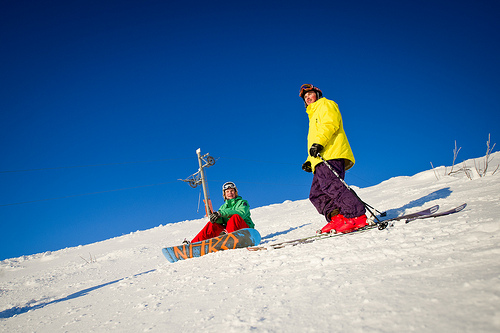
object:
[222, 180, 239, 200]
helmet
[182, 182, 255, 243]
boy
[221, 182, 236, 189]
googles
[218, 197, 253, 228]
jacket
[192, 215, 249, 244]
pants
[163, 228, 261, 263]
snowboard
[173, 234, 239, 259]
letters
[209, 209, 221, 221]
gloves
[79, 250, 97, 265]
weeds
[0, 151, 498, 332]
snow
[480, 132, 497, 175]
branches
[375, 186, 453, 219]
shadow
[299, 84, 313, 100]
googles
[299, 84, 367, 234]
man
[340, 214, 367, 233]
boots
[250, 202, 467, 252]
skis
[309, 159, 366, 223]
pants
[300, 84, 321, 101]
helmet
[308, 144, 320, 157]
glove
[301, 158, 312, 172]
glove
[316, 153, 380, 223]
pole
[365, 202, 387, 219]
pole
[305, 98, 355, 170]
jecket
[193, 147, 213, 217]
pole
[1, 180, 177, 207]
wires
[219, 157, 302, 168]
wires